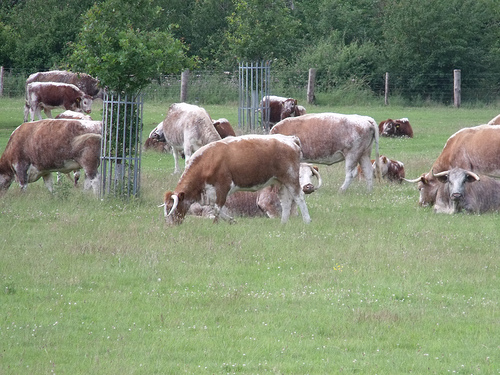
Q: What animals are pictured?
A: Cows.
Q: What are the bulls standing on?
A: Grass.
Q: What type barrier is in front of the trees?
A: Fence.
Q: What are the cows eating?
A: Grass.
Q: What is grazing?
A: Cow.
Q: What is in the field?
A: Grass.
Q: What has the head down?
A: Bull.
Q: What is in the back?
A: Fence.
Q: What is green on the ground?
A: Grass.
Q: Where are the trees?
A: Around the field.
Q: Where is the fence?
A: Surrounding the pasture.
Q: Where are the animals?
A: In the field.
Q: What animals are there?
A: Cow.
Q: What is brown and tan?
A: The cow.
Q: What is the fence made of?
A: Wood and metal.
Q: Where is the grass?
A: The ground.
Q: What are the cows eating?
A: Grass.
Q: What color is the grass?
A: Green.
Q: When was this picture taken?
A: Daytime.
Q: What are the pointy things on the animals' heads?
A: Horns.